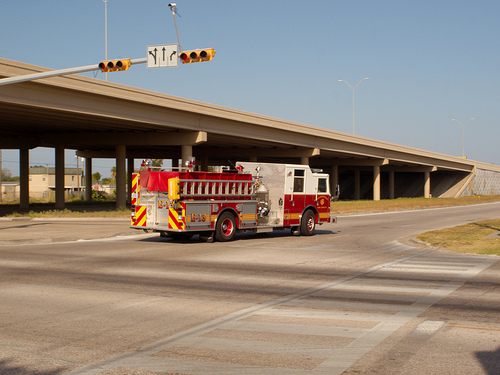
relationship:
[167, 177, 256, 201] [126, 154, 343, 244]
ladder on side of fire truck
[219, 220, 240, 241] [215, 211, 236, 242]
rim on tire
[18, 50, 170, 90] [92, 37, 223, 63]
pole holding traffic lights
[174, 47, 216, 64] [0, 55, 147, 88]
traffic licght on pole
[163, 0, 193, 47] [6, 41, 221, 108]
camera attached to pole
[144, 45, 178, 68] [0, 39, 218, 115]
sign on pole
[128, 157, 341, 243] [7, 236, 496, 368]
fire truck on road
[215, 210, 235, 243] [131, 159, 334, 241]
tire on truck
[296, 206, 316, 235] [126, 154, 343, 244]
tire on fire truck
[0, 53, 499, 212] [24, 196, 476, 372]
bridge over road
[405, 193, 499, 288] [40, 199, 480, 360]
grass on ground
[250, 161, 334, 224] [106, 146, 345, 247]
cab on front of fire truck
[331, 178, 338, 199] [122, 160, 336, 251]
mirror on side of truck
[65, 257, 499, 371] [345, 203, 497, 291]
crosswalk on road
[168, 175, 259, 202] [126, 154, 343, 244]
ladder on fire truck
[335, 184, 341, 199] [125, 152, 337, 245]
mirror on firetruck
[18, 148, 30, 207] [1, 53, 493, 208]
column supporting bridge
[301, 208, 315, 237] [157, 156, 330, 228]
tire on truck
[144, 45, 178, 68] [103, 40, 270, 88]
sign on traffic light